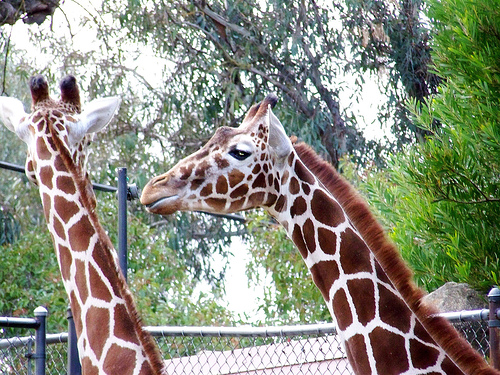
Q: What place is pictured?
A: It is a zoo.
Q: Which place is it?
A: It is a zoo.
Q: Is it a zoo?
A: Yes, it is a zoo.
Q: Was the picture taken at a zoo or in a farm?
A: It was taken at a zoo.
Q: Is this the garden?
A: No, it is the zoo.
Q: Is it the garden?
A: No, it is the zoo.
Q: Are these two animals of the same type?
A: Yes, all the animals are giraffes.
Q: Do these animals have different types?
A: No, all the animals are giraffes.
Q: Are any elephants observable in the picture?
A: No, there are no elephants.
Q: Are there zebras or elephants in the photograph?
A: No, there are no elephants or zebras.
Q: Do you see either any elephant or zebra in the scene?
A: No, there are no elephants or zebras.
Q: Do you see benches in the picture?
A: No, there are no benches.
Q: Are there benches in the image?
A: No, there are no benches.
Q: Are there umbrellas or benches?
A: No, there are no benches or umbrellas.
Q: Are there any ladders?
A: No, there are no ladders.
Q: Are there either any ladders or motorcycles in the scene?
A: No, there are no ladders or motorcycles.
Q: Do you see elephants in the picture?
A: No, there are no elephants.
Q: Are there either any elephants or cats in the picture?
A: No, there are no elephants or cats.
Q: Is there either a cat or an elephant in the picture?
A: No, there are no elephants or cats.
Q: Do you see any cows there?
A: No, there are no cows.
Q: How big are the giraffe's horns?
A: The horns are small.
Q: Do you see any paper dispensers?
A: No, there are no paper dispensers.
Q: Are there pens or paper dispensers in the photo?
A: No, there are no paper dispensers or pens.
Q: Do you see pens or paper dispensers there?
A: No, there are no paper dispensers or pens.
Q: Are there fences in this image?
A: Yes, there is a fence.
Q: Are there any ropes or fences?
A: Yes, there is a fence.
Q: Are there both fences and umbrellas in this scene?
A: No, there is a fence but no umbrellas.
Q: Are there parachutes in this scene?
A: No, there are no parachutes.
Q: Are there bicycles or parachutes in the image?
A: No, there are no parachutes or bicycles.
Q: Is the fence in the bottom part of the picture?
A: Yes, the fence is in the bottom of the image.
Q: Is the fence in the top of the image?
A: No, the fence is in the bottom of the image.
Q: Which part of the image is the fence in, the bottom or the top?
A: The fence is in the bottom of the image.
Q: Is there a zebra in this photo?
A: No, there are no zebras.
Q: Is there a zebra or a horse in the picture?
A: No, there are no zebras or horses.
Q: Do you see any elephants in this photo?
A: No, there are no elephants.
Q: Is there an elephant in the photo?
A: No, there are no elephants.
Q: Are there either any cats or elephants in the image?
A: No, there are no elephants or cats.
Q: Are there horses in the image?
A: No, there are no horses.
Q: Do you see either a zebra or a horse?
A: No, there are no horses or zebras.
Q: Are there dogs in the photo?
A: No, there are no dogs.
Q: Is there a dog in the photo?
A: No, there are no dogs.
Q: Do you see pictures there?
A: No, there are no pictures.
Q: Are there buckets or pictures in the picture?
A: No, there are no pictures or buckets.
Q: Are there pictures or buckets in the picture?
A: No, there are no pictures or buckets.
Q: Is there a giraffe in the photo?
A: Yes, there is a giraffe.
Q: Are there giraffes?
A: Yes, there is a giraffe.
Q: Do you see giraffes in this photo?
A: Yes, there is a giraffe.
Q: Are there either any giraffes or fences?
A: Yes, there is a giraffe.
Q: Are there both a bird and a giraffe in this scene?
A: No, there is a giraffe but no birds.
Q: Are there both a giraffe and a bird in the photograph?
A: No, there is a giraffe but no birds.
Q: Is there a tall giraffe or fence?
A: Yes, there is a tall giraffe.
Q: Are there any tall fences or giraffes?
A: Yes, there is a tall giraffe.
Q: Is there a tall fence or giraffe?
A: Yes, there is a tall giraffe.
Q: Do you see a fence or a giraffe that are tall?
A: Yes, the giraffe is tall.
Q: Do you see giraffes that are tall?
A: Yes, there is a tall giraffe.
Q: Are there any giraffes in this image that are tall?
A: Yes, there is a giraffe that is tall.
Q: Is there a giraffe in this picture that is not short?
A: Yes, there is a tall giraffe.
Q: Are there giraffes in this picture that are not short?
A: Yes, there is a tall giraffe.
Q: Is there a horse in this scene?
A: No, there are no horses.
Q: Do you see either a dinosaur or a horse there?
A: No, there are no horses or dinosaurs.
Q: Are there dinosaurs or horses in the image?
A: No, there are no horses or dinosaurs.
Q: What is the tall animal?
A: The animal is a giraffe.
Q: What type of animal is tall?
A: The animal is a giraffe.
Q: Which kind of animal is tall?
A: The animal is a giraffe.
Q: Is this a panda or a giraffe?
A: This is a giraffe.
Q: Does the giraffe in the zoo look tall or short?
A: The giraffe is tall.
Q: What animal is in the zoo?
A: The giraffe is in the zoo.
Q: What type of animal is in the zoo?
A: The animal is a giraffe.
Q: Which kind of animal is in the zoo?
A: The animal is a giraffe.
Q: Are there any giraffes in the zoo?
A: Yes, there is a giraffe in the zoo.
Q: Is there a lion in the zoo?
A: No, there is a giraffe in the zoo.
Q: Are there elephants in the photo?
A: No, there are no elephants.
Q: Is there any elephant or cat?
A: No, there are no elephants or cats.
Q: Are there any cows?
A: No, there are no cows.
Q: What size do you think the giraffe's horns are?
A: The horns are small.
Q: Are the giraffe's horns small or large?
A: The horns are small.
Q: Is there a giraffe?
A: Yes, there is a giraffe.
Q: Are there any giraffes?
A: Yes, there is a giraffe.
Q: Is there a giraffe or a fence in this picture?
A: Yes, there is a giraffe.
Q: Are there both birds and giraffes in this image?
A: No, there is a giraffe but no birds.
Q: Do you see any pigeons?
A: No, there are no pigeons.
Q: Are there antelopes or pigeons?
A: No, there are no pigeons or antelopes.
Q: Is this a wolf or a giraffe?
A: This is a giraffe.